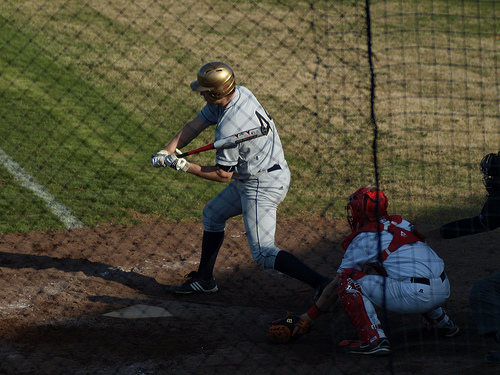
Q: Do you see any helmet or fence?
A: Yes, there is a helmet.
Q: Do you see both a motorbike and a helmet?
A: No, there is a helmet but no motorcycles.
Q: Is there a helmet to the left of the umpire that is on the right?
A: Yes, there is a helmet to the left of the umpire.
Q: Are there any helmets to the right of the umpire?
A: No, the helmet is to the left of the umpire.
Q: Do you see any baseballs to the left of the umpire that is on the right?
A: No, there is a helmet to the left of the umpire.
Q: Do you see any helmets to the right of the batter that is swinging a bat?
A: Yes, there is a helmet to the right of the batter.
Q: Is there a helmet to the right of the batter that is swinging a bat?
A: Yes, there is a helmet to the right of the batter.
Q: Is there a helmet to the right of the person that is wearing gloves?
A: Yes, there is a helmet to the right of the batter.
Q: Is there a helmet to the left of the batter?
A: No, the helmet is to the right of the batter.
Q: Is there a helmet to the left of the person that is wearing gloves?
A: No, the helmet is to the right of the batter.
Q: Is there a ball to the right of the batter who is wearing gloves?
A: No, there is a helmet to the right of the batter.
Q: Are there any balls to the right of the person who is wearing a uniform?
A: No, there is a helmet to the right of the batter.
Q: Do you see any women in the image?
A: No, there are no women.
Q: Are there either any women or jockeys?
A: No, there are no women or jockeys.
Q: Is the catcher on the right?
A: Yes, the catcher is on the right of the image.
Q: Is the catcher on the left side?
A: No, the catcher is on the right of the image.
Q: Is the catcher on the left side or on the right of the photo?
A: The catcher is on the right of the image.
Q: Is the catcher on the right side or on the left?
A: The catcher is on the right of the image.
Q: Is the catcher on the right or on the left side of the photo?
A: The catcher is on the right of the image.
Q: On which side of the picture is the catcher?
A: The catcher is on the right of the image.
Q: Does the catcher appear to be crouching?
A: Yes, the catcher is crouching.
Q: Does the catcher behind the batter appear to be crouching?
A: Yes, the catcher is crouching.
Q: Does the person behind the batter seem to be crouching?
A: Yes, the catcher is crouching.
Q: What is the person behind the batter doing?
A: The catcher is crouching.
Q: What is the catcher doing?
A: The catcher is crouching.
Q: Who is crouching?
A: The catcher is crouching.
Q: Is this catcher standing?
A: No, the catcher is crouching.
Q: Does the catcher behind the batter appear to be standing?
A: No, the catcher is crouching.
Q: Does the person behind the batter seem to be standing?
A: No, the catcher is crouching.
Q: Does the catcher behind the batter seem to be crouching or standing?
A: The catcher is crouching.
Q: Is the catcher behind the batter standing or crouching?
A: The catcher is crouching.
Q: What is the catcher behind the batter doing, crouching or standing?
A: The catcher is crouching.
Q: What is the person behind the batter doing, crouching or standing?
A: The catcher is crouching.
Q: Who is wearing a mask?
A: The catcher is wearing a mask.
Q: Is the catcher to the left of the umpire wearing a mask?
A: Yes, the catcher is wearing a mask.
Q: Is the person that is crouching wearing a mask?
A: Yes, the catcher is wearing a mask.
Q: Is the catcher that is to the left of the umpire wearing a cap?
A: No, the catcher is wearing a mask.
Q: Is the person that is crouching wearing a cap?
A: No, the catcher is wearing a mask.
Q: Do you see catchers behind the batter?
A: Yes, there is a catcher behind the batter.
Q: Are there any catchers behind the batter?
A: Yes, there is a catcher behind the batter.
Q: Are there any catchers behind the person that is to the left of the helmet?
A: Yes, there is a catcher behind the batter.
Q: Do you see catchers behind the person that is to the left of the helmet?
A: Yes, there is a catcher behind the batter.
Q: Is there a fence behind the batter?
A: No, there is a catcher behind the batter.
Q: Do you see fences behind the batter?
A: No, there is a catcher behind the batter.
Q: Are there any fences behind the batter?
A: No, there is a catcher behind the batter.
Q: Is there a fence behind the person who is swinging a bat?
A: No, there is a catcher behind the batter.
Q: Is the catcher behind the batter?
A: Yes, the catcher is behind the batter.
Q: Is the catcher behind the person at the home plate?
A: Yes, the catcher is behind the batter.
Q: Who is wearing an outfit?
A: The catcher is wearing an outfit.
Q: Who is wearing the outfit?
A: The catcher is wearing an outfit.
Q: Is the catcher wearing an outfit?
A: Yes, the catcher is wearing an outfit.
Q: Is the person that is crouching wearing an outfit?
A: Yes, the catcher is wearing an outfit.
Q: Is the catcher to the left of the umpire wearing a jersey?
A: No, the catcher is wearing an outfit.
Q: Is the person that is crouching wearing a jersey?
A: No, the catcher is wearing an outfit.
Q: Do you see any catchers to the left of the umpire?
A: Yes, there is a catcher to the left of the umpire.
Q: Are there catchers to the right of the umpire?
A: No, the catcher is to the left of the umpire.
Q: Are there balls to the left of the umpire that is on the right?
A: No, there is a catcher to the left of the umpire.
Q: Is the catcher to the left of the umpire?
A: Yes, the catcher is to the left of the umpire.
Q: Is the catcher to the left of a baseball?
A: No, the catcher is to the left of the umpire.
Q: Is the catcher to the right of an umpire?
A: No, the catcher is to the left of an umpire.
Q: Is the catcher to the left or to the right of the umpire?
A: The catcher is to the left of the umpire.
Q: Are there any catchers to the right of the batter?
A: Yes, there is a catcher to the right of the batter.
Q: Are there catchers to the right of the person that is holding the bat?
A: Yes, there is a catcher to the right of the batter.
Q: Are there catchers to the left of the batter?
A: No, the catcher is to the right of the batter.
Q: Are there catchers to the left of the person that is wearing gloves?
A: No, the catcher is to the right of the batter.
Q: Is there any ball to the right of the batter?
A: No, there is a catcher to the right of the batter.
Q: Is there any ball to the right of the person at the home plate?
A: No, there is a catcher to the right of the batter.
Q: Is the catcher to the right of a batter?
A: Yes, the catcher is to the right of a batter.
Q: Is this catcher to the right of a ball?
A: No, the catcher is to the right of a batter.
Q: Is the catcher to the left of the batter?
A: No, the catcher is to the right of the batter.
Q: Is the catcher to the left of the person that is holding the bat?
A: No, the catcher is to the right of the batter.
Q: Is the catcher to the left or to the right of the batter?
A: The catcher is to the right of the batter.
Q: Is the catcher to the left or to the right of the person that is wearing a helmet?
A: The catcher is to the right of the batter.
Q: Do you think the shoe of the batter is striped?
A: Yes, the shoe is striped.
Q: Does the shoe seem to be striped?
A: Yes, the shoe is striped.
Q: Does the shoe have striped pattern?
A: Yes, the shoe is striped.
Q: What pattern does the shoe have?
A: The shoe has striped pattern.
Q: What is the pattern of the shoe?
A: The shoe is striped.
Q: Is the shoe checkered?
A: No, the shoe is striped.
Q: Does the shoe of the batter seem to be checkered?
A: No, the shoe is striped.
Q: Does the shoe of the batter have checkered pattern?
A: No, the shoe is striped.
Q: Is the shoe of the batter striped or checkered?
A: The shoe is striped.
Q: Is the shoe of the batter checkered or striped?
A: The shoe is striped.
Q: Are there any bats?
A: Yes, there is a bat.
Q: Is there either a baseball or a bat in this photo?
A: Yes, there is a bat.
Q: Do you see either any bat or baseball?
A: Yes, there is a bat.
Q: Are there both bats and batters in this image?
A: Yes, there are both a bat and a batter.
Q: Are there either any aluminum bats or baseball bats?
A: Yes, there is an aluminum bat.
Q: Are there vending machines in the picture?
A: No, there are no vending machines.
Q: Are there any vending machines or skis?
A: No, there are no vending machines or skis.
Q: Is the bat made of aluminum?
A: Yes, the bat is made of aluminum.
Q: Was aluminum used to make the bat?
A: Yes, the bat is made of aluminum.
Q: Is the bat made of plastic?
A: No, the bat is made of aluminum.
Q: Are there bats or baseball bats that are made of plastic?
A: No, there is a bat but it is made of aluminum.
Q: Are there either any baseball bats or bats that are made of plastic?
A: No, there is a bat but it is made of aluminum.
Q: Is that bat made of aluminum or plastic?
A: The bat is made of aluminum.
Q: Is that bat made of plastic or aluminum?
A: The bat is made of aluminum.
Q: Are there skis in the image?
A: No, there are no skis.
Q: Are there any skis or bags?
A: No, there are no skis or bags.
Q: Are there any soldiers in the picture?
A: No, there are no soldiers.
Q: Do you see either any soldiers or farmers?
A: No, there are no soldiers or farmers.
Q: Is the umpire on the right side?
A: Yes, the umpire is on the right of the image.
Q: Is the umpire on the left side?
A: No, the umpire is on the right of the image.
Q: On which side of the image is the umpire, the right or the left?
A: The umpire is on the right of the image.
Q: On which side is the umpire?
A: The umpire is on the right of the image.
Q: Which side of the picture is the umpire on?
A: The umpire is on the right of the image.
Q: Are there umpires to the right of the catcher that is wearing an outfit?
A: Yes, there is an umpire to the right of the catcher.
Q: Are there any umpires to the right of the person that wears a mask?
A: Yes, there is an umpire to the right of the catcher.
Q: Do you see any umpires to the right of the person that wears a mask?
A: Yes, there is an umpire to the right of the catcher.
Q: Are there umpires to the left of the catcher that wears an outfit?
A: No, the umpire is to the right of the catcher.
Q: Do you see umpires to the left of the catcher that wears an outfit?
A: No, the umpire is to the right of the catcher.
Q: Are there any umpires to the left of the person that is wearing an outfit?
A: No, the umpire is to the right of the catcher.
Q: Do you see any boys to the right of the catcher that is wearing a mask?
A: No, there is an umpire to the right of the catcher.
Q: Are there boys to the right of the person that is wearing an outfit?
A: No, there is an umpire to the right of the catcher.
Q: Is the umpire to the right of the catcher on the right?
A: Yes, the umpire is to the right of the catcher.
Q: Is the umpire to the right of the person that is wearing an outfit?
A: Yes, the umpire is to the right of the catcher.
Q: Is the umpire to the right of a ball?
A: No, the umpire is to the right of the catcher.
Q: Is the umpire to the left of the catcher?
A: No, the umpire is to the right of the catcher.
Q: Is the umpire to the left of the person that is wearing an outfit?
A: No, the umpire is to the right of the catcher.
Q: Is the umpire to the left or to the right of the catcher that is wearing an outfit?
A: The umpire is to the right of the catcher.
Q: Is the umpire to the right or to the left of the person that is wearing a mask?
A: The umpire is to the right of the catcher.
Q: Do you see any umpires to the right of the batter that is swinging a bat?
A: Yes, there is an umpire to the right of the batter.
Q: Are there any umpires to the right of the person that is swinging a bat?
A: Yes, there is an umpire to the right of the batter.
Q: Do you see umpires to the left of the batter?
A: No, the umpire is to the right of the batter.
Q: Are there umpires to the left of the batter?
A: No, the umpire is to the right of the batter.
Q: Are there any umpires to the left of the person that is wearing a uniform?
A: No, the umpire is to the right of the batter.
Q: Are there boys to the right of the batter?
A: No, there is an umpire to the right of the batter.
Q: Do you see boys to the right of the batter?
A: No, there is an umpire to the right of the batter.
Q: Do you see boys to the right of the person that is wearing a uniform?
A: No, there is an umpire to the right of the batter.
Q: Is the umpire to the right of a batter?
A: Yes, the umpire is to the right of a batter.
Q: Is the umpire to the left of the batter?
A: No, the umpire is to the right of the batter.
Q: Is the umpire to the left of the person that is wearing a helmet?
A: No, the umpire is to the right of the batter.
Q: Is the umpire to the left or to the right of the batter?
A: The umpire is to the right of the batter.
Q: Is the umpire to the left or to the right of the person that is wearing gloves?
A: The umpire is to the right of the batter.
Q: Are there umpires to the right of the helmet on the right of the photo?
A: Yes, there is an umpire to the right of the helmet.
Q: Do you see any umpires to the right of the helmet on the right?
A: Yes, there is an umpire to the right of the helmet.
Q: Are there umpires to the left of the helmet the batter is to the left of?
A: No, the umpire is to the right of the helmet.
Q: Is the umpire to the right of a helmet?
A: Yes, the umpire is to the right of a helmet.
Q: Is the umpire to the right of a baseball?
A: No, the umpire is to the right of a helmet.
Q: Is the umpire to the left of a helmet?
A: No, the umpire is to the right of a helmet.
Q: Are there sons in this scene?
A: No, there are no sons.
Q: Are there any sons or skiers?
A: No, there are no sons or skiers.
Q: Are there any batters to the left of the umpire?
A: Yes, there is a batter to the left of the umpire.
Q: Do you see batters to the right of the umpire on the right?
A: No, the batter is to the left of the umpire.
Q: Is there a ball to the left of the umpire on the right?
A: No, there is a batter to the left of the umpire.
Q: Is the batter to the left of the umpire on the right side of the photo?
A: Yes, the batter is to the left of the umpire.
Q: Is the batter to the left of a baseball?
A: No, the batter is to the left of the umpire.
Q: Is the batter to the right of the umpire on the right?
A: No, the batter is to the left of the umpire.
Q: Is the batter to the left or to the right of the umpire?
A: The batter is to the left of the umpire.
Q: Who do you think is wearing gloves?
A: The batter is wearing gloves.